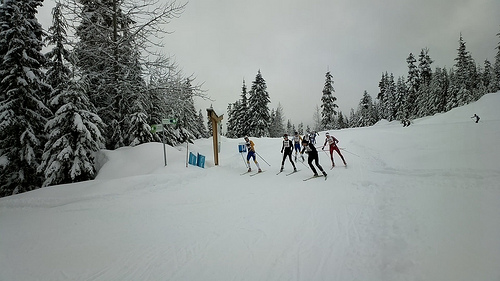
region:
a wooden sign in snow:
[199, 102, 226, 167]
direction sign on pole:
[148, 113, 177, 168]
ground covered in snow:
[0, 90, 498, 279]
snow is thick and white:
[1, 85, 498, 279]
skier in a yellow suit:
[233, 125, 273, 182]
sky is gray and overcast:
[25, 1, 499, 133]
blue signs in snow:
[186, 148, 209, 175]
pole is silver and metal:
[156, 115, 170, 170]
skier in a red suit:
[320, 129, 354, 173]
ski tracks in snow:
[285, 164, 400, 279]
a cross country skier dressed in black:
[298, 138, 328, 184]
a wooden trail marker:
[206, 108, 221, 166]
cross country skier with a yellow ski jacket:
[239, 135, 270, 177]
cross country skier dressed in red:
[322, 133, 348, 168]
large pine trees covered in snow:
[223, 29, 497, 130]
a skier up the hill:
[466, 110, 484, 123]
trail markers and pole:
[150, 114, 173, 166]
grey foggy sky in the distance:
[153, 0, 498, 69]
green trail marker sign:
[160, 115, 170, 122]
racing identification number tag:
[282, 138, 290, 148]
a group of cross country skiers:
[235, 113, 355, 185]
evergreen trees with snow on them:
[37, 58, 102, 172]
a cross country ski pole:
[342, 145, 361, 162]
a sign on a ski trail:
[202, 103, 234, 171]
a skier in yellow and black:
[241, 131, 274, 178]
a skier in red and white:
[321, 130, 348, 167]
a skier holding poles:
[233, 145, 272, 170]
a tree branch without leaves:
[140, 8, 177, 51]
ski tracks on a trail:
[270, 221, 357, 271]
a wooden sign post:
[202, 106, 227, 162]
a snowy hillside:
[3, 93, 495, 275]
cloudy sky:
[138, 3, 496, 125]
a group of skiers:
[236, 123, 356, 181]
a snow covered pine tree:
[27, 2, 112, 183]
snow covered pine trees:
[3, 6, 496, 195]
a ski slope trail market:
[150, 115, 174, 171]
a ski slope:
[125, 93, 494, 280]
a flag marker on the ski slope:
[236, 138, 250, 173]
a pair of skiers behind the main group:
[397, 111, 416, 132]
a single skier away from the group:
[466, 108, 483, 128]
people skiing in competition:
[237, 113, 482, 183]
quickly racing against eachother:
[237, 108, 482, 180]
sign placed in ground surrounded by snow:
[149, 112, 172, 172]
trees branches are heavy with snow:
[1, 0, 202, 193]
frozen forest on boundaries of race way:
[1, 0, 202, 194]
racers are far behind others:
[398, 110, 482, 127]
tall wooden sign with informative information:
[203, 103, 223, 168]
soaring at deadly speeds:
[240, 129, 345, 186]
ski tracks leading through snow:
[85, 162, 494, 279]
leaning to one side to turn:
[237, 131, 271, 177]